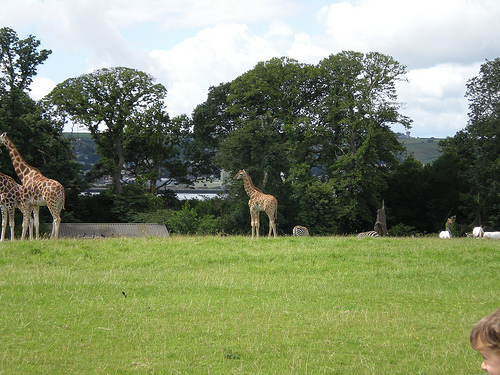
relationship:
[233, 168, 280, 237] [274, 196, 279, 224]
giraffe has a tail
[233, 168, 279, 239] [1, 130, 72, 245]
giraffe of a giraffe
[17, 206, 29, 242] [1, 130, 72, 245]
leg of a giraffe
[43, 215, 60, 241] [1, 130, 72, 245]
leg of a giraffe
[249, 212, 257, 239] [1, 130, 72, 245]
leg of a giraffe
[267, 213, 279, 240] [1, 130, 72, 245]
leg of a giraffe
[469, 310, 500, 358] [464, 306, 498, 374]
hair on a head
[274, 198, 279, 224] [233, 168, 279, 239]
tail on giraffe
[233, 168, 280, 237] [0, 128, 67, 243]
giraffe standing in a giraffe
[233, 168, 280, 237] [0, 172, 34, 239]
giraffe standing in a giraffe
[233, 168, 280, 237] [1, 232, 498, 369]
giraffe standing in a field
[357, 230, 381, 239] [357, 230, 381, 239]
zebra grazing near zebra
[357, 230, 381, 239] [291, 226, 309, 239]
zebra grazing near zebra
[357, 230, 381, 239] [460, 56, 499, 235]
zebra grazing near trees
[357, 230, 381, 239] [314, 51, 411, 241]
zebra grazing near trees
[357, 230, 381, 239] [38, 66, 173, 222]
zebra grazing near trees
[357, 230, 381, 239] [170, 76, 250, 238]
zebra grazing near trees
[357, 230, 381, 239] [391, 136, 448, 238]
zebra grazing near trees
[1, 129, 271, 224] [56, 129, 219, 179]
building with a roof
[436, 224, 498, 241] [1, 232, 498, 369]
white animals in a field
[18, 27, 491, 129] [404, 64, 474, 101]
sky full of clouds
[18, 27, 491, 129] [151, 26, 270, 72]
sky full of clouds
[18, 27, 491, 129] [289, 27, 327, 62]
sky full of clouds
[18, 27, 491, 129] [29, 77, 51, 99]
sky full of clouds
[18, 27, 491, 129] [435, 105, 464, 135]
sky full of clouds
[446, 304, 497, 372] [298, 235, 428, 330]
boy looking in field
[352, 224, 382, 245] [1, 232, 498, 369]
zebra grazing in field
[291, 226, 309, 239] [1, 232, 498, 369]
zebra grazing in field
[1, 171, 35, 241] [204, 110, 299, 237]
giraffe stand on side of tree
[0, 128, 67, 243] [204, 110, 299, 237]
giraffe stand on side of tree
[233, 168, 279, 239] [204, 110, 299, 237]
giraffe stand on side of tree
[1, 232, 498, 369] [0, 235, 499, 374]
field covered with grass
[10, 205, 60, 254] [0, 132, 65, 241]
leg on giraffe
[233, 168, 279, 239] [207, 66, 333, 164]
giraffe under tree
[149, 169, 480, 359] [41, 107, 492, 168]
landscape behind field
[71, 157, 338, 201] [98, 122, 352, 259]
building in background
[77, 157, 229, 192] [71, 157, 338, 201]
roof of building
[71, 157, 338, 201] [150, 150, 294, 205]
building in background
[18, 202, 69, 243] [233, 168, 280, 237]
legs of giraffe